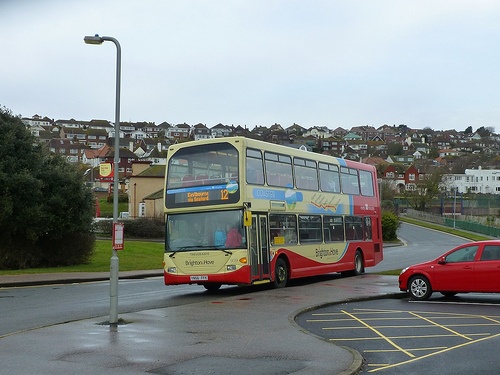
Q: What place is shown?
A: It is a street.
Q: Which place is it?
A: It is a street.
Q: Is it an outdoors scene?
A: Yes, it is outdoors.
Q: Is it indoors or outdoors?
A: It is outdoors.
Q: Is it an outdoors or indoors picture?
A: It is outdoors.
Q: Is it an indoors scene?
A: No, it is outdoors.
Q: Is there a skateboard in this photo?
A: No, there are no skateboards.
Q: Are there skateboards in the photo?
A: No, there are no skateboards.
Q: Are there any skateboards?
A: No, there are no skateboards.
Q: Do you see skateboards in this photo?
A: No, there are no skateboards.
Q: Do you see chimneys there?
A: No, there are no chimneys.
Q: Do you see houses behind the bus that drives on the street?
A: Yes, there is a house behind the bus.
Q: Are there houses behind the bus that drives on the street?
A: Yes, there is a house behind the bus.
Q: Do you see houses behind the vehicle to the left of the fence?
A: Yes, there is a house behind the bus.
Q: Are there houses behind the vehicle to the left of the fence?
A: Yes, there is a house behind the bus.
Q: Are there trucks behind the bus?
A: No, there is a house behind the bus.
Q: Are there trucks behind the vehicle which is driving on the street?
A: No, there is a house behind the bus.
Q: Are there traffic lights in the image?
A: No, there are no traffic lights.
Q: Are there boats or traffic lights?
A: No, there are no traffic lights or boats.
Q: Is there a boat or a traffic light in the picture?
A: No, there are no traffic lights or boats.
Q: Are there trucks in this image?
A: No, there are no trucks.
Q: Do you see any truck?
A: No, there are no trucks.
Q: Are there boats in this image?
A: No, there are no boats.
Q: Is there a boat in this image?
A: No, there are no boats.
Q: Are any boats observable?
A: No, there are no boats.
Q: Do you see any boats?
A: No, there are no boats.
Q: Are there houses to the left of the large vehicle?
A: Yes, there are houses to the left of the bus.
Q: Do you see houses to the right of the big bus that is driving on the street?
A: No, the houses are to the left of the bus.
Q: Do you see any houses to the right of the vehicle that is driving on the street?
A: No, the houses are to the left of the bus.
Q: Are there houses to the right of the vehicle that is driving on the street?
A: No, the houses are to the left of the bus.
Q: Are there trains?
A: No, there are no trains.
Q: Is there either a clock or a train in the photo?
A: No, there are no trains or clocks.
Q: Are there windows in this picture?
A: Yes, there is a window.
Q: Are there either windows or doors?
A: Yes, there is a window.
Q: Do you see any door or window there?
A: Yes, there is a window.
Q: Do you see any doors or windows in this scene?
A: Yes, there is a window.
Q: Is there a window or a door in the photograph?
A: Yes, there is a window.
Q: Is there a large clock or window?
A: Yes, there is a large window.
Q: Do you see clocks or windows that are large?
A: Yes, the window is large.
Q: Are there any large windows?
A: Yes, there is a large window.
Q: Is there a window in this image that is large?
A: Yes, there is a window that is large.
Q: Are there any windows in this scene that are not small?
A: Yes, there is a large window.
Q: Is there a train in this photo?
A: No, there are no trains.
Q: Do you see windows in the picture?
A: Yes, there is a window.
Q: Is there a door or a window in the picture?
A: Yes, there is a window.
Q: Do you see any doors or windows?
A: Yes, there is a window.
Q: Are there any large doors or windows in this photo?
A: Yes, there is a large window.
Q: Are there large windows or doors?
A: Yes, there is a large window.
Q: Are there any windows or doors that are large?
A: Yes, the window is large.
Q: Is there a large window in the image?
A: Yes, there is a large window.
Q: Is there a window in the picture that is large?
A: Yes, there is a window that is large.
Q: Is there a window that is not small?
A: Yes, there is a large window.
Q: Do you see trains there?
A: No, there are no trains.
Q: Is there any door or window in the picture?
A: Yes, there is a window.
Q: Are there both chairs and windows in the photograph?
A: No, there is a window but no chairs.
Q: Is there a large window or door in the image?
A: Yes, there is a large window.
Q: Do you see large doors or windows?
A: Yes, there is a large window.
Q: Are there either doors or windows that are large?
A: Yes, the window is large.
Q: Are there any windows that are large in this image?
A: Yes, there is a large window.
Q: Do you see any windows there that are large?
A: Yes, there is a window that is large.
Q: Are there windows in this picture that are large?
A: Yes, there is a window that is large.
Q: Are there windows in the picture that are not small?
A: Yes, there is a large window.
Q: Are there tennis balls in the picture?
A: No, there are no tennis balls.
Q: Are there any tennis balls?
A: No, there are no tennis balls.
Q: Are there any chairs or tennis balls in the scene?
A: No, there are no tennis balls or chairs.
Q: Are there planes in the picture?
A: No, there are no planes.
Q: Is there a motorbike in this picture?
A: No, there are no motorcycles.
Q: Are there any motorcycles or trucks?
A: No, there are no motorcycles or trucks.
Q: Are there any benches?
A: No, there are no benches.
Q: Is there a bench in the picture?
A: No, there are no benches.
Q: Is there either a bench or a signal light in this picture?
A: No, there are no benches or traffic lights.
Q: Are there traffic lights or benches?
A: No, there are no benches or traffic lights.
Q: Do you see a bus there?
A: Yes, there is a bus.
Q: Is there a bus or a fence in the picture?
A: Yes, there is a bus.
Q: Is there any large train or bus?
A: Yes, there is a large bus.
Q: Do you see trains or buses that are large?
A: Yes, the bus is large.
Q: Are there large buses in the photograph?
A: Yes, there is a large bus.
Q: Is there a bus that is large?
A: Yes, there is a bus that is large.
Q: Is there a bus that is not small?
A: Yes, there is a large bus.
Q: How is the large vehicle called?
A: The vehicle is a bus.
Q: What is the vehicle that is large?
A: The vehicle is a bus.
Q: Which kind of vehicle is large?
A: The vehicle is a bus.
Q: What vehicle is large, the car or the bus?
A: The bus is large.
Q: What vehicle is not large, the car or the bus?
A: The car is not large.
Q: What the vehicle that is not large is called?
A: The vehicle is a car.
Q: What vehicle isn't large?
A: The vehicle is a car.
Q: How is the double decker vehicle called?
A: The vehicle is a bus.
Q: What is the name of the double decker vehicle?
A: The vehicle is a bus.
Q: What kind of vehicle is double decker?
A: The vehicle is a bus.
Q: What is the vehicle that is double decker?
A: The vehicle is a bus.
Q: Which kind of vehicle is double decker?
A: The vehicle is a bus.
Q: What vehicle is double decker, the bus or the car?
A: The bus is double decker.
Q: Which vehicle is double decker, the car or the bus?
A: The bus is double decker.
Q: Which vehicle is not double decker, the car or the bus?
A: The car is not double decker.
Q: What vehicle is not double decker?
A: The vehicle is a car.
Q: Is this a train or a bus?
A: This is a bus.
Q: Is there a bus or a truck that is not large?
A: No, there is a bus but it is large.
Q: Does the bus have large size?
A: Yes, the bus is large.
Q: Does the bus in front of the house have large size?
A: Yes, the bus is large.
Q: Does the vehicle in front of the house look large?
A: Yes, the bus is large.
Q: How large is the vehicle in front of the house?
A: The bus is large.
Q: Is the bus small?
A: No, the bus is large.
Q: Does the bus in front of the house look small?
A: No, the bus is large.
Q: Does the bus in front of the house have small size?
A: No, the bus is large.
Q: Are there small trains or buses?
A: No, there is a bus but it is large.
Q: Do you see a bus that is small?
A: No, there is a bus but it is large.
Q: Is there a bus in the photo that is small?
A: No, there is a bus but it is large.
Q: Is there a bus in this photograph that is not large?
A: No, there is a bus but it is large.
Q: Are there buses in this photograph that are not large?
A: No, there is a bus but it is large.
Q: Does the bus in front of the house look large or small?
A: The bus is large.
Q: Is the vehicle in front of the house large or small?
A: The bus is large.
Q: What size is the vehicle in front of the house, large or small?
A: The bus is large.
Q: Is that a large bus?
A: Yes, that is a large bus.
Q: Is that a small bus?
A: No, that is a large bus.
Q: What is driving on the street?
A: The bus is driving on the street.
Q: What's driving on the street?
A: The bus is driving on the street.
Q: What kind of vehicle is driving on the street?
A: The vehicle is a bus.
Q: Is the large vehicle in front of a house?
A: Yes, the bus is in front of a house.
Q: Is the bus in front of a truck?
A: No, the bus is in front of a house.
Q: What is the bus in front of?
A: The bus is in front of the house.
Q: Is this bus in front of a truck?
A: No, the bus is in front of a house.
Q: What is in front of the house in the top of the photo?
A: The bus is in front of the house.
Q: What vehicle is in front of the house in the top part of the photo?
A: The vehicle is a bus.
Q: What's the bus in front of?
A: The bus is in front of the house.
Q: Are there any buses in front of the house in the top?
A: Yes, there is a bus in front of the house.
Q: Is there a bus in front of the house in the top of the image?
A: Yes, there is a bus in front of the house.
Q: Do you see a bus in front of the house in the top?
A: Yes, there is a bus in front of the house.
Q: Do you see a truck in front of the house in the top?
A: No, there is a bus in front of the house.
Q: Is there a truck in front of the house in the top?
A: No, there is a bus in front of the house.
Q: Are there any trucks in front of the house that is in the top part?
A: No, there is a bus in front of the house.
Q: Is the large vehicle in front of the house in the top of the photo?
A: Yes, the bus is in front of the house.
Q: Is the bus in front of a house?
A: Yes, the bus is in front of a house.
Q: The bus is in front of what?
A: The bus is in front of the house.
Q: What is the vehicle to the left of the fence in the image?
A: The vehicle is a bus.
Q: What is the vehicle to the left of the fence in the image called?
A: The vehicle is a bus.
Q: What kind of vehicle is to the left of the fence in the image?
A: The vehicle is a bus.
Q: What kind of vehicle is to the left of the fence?
A: The vehicle is a bus.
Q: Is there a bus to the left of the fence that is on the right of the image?
A: Yes, there is a bus to the left of the fence.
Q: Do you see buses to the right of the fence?
A: No, the bus is to the left of the fence.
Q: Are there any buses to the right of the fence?
A: No, the bus is to the left of the fence.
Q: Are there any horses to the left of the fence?
A: No, there is a bus to the left of the fence.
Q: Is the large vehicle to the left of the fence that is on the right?
A: Yes, the bus is to the left of the fence.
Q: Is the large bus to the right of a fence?
A: No, the bus is to the left of a fence.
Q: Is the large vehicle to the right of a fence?
A: No, the bus is to the left of a fence.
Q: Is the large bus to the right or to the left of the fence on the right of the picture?
A: The bus is to the left of the fence.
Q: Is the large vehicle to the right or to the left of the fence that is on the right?
A: The bus is to the left of the fence.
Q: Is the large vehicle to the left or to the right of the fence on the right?
A: The bus is to the left of the fence.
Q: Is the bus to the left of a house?
A: Yes, the bus is to the left of a house.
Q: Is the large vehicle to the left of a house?
A: Yes, the bus is to the left of a house.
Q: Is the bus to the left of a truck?
A: No, the bus is to the left of a house.